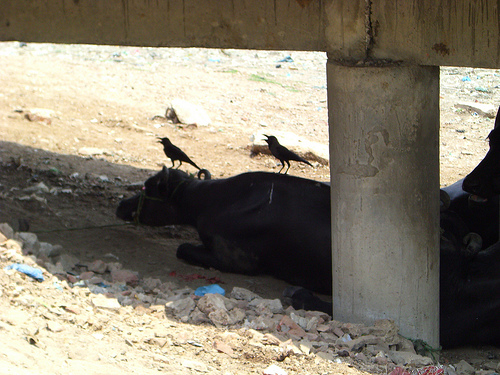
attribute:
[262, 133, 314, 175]
bird — black, singing, cawing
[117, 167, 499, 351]
cow — laying, black, lying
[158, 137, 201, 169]
bird — mouth open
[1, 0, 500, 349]
bridge — cement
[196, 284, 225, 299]
trash — blue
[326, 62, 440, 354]
column — round, large, concrete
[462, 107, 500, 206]
cow — brown